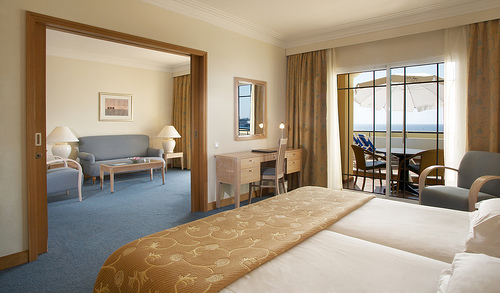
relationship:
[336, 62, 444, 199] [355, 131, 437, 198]
window overlooking patio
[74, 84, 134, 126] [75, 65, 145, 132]
painting on wall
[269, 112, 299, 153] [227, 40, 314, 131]
desk lamp on corner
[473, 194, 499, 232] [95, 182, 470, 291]
pillow on bed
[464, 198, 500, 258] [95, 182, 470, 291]
pillow on bed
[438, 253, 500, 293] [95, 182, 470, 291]
pillow on bed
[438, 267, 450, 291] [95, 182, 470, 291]
pillow on bed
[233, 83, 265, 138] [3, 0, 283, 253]
mirror on wall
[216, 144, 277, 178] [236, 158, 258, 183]
desk has drawers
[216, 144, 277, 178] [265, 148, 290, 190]
desk has chair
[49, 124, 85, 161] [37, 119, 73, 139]
lamp with shade